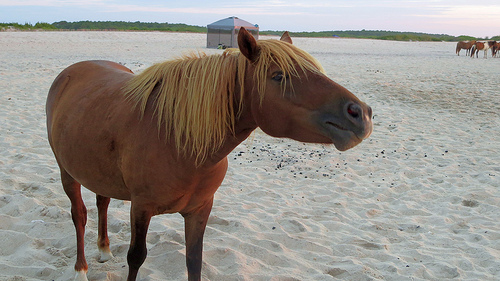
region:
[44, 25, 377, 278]
a brown pony stands on the sand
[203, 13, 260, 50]
a tent-like structure on th sand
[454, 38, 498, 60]
several horses are standing away on the sand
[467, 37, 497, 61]
a brown and white horse standing in the sand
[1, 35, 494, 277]
footprints in the sand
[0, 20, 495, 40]
grass and trees grass and trees above the sand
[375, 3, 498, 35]
blue sky with a bit of light pink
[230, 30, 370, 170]
head of the horse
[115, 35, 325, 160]
mane of horse is blond and brown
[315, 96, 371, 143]
mouth and nose of the horse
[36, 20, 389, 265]
horse with blonde mane on the beach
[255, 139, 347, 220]
footprints and trash in the sand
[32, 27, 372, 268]
brown horse standing on the sand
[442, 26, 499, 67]
group of horses on the sandy beach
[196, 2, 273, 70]
small shaded tent on the beach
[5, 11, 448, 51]
long green hills behind the beach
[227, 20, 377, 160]
horse face with blonde mane and black around mouth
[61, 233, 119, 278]
white hair near the horse's feet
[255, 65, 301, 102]
horse has brown eye under mane hair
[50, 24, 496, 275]
horses in the sand on the beach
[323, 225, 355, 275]
aprt of a neach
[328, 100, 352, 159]
part of a mouth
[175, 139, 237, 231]
part of a chesr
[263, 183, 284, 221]
part of a ground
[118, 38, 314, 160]
horse has yellow hair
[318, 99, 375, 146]
dark brown nose and mouth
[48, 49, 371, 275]
a brown horse standing on the beach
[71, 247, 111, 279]
two white feet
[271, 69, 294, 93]
hair is over the horse's eye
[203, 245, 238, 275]
footprint in the sand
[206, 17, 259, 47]
pop up tent on the beach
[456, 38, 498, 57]
horses standing on the sand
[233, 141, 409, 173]
black specs on the sand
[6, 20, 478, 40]
a green hill side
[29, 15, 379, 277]
brown horse standing on sand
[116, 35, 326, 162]
blonde straight hair on back of horse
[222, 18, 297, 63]
two pointed horse ears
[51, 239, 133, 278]
two white horse hooves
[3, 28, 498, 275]
large body of tan sand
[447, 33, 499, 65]
several horses standing together on sand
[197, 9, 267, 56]
tent in center of sand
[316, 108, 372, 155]
dark nose mouth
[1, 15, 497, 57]
green trees bordering sand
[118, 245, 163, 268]
dark horse knee